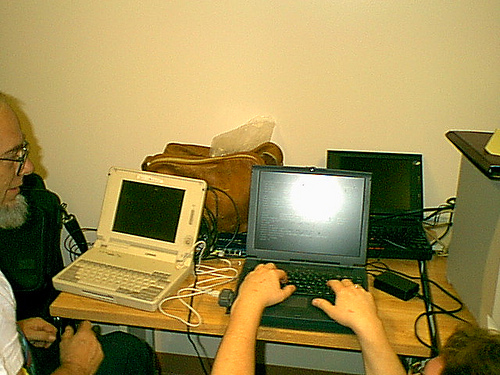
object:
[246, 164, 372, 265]
computer screen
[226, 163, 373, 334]
lap top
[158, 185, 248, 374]
cords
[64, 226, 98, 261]
cords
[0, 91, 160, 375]
man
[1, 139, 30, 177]
glasses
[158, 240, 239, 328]
white wires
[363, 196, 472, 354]
cord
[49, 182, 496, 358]
table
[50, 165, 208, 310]
laptop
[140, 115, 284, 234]
case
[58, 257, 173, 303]
keyboard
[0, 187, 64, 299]
bag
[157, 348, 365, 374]
ground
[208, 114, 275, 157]
plastic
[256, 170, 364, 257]
glare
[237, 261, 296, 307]
hands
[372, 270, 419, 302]
power brick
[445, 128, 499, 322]
container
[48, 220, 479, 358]
desk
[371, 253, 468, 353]
space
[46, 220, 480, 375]
tables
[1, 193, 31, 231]
beard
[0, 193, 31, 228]
hair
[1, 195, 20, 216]
chin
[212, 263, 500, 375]
person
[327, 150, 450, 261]
laptop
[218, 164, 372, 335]
laptop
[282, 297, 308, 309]
touchpad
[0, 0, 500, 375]
photo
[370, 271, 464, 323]
scrolling